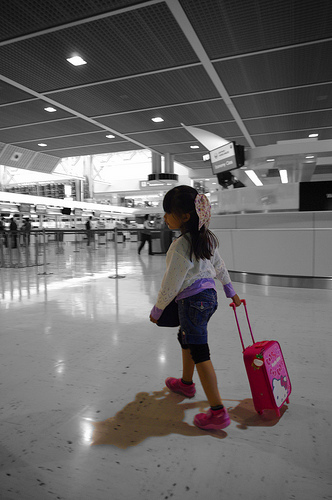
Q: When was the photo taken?
A: Daytime.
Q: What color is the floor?
A: White.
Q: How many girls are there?
A: One.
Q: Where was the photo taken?
A: At the airport.